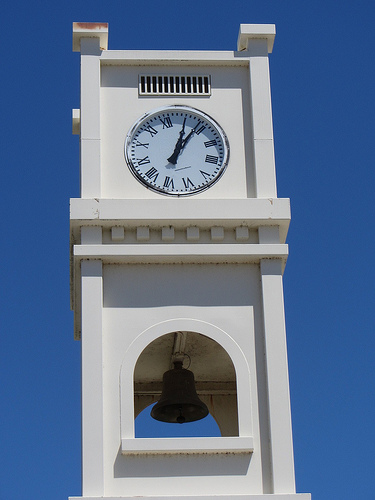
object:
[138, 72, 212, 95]
grate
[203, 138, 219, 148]
3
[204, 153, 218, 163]
four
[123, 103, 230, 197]
clock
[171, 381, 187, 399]
metal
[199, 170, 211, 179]
roman numeral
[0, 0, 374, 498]
sky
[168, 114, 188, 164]
hands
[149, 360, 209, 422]
bell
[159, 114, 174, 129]
roman numeral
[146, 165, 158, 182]
roman numeral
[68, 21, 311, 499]
bell tower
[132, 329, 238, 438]
window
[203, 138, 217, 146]
numeral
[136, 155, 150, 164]
numeral